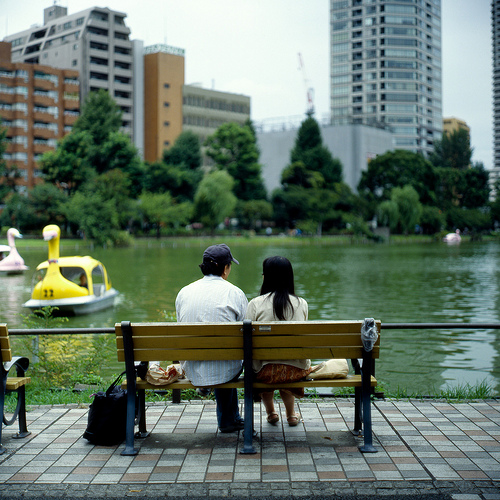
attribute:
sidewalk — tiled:
[4, 396, 498, 497]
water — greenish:
[12, 243, 496, 402]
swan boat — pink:
[1, 221, 28, 280]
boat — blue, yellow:
[18, 216, 121, 316]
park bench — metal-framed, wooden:
[109, 314, 388, 438]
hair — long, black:
[254, 249, 300, 319]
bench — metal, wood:
[102, 309, 406, 464]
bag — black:
[83, 377, 150, 447]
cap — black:
[200, 231, 246, 271]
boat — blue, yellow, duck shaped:
[22, 208, 118, 334]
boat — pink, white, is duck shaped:
[4, 213, 23, 277]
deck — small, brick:
[8, 376, 484, 498]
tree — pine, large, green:
[253, 78, 393, 270]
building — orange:
[6, 14, 245, 213]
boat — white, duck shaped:
[5, 224, 25, 283]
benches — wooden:
[76, 300, 397, 469]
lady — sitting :
[235, 251, 316, 429]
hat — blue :
[196, 239, 243, 275]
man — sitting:
[174, 242, 253, 438]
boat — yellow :
[25, 220, 120, 314]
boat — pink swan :
[4, 221, 31, 281]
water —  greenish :
[326, 244, 444, 293]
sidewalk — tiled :
[8, 403, 484, 473]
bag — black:
[78, 359, 140, 446]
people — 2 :
[171, 244, 325, 429]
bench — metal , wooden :
[94, 307, 381, 454]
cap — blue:
[201, 242, 282, 286]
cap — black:
[195, 242, 245, 263]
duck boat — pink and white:
[0, 223, 30, 277]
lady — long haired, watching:
[230, 243, 379, 434]